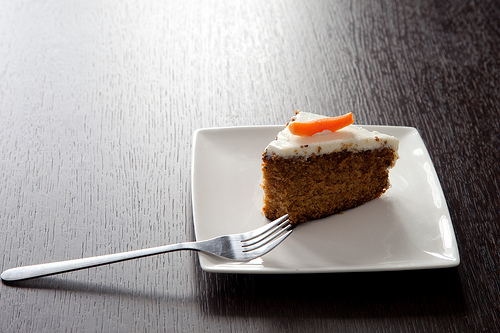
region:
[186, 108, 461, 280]
slice of cake on a table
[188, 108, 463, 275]
piece of cake on a plate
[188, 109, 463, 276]
carrot cake on a plate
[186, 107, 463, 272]
slice of carrot cake on a plate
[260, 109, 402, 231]
carrot cake with a white icing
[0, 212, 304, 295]
silver fork on a plate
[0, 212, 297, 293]
silver fork on a table and plate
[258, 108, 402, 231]
small portion of carrot cake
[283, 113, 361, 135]
carrot topping on a cake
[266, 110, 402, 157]
white cake icing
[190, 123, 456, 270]
A slice of cake on top of a white plate.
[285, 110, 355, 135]
Piece of a carrot on top of the frosting.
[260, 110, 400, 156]
White frosting on top of the cake.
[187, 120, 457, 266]
Plate is square shaped.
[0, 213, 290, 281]
A silver fork leaning on the plate.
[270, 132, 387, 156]
Crumbs from the cake on the frosting.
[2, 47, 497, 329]
White plate on a brown wooden surface.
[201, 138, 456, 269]
Light reflecting off of the edges of the plate.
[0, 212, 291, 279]
Light reflecting off of the fork.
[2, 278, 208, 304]
Shadow of the fork on the wooden surface.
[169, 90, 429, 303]
a piece of cake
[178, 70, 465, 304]
a piece of cake on a white plate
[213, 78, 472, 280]
a piece of cake on a plate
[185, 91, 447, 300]
a white plate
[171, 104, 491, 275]
a white plate with food on it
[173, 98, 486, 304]
a white plate with a piece of cake on it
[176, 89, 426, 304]
a plate with cake on it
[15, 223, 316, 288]
a silver fork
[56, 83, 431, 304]
a silver fork on a plate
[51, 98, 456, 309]
a silver fork on a white plate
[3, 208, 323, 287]
Silver fork on table and plate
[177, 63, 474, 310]
White dish with fork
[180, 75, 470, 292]
White dish with cake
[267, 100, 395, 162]
White iceing on cake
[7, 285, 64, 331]
Dark brown wood grain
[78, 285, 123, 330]
Dark brown wood grain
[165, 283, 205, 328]
Dark brown wood grain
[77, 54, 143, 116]
Dark brown wood grain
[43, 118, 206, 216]
Dark brown wood grain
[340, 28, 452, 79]
Dark brown wood grain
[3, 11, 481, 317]
black table with short dark lines in same direction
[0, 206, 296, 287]
fork resting on corner of white plate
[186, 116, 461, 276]
slice of carrot cake on white plate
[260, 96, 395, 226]
white icing with piece of carrot on top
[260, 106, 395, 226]
wedge of orangey-brown cake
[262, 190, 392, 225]
dark crust at bottom of cake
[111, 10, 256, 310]
bright light shining on table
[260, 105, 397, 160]
dark crumb bits on edge of icing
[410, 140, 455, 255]
light reflecting on side of plate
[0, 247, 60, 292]
curved edge at end of fork handle